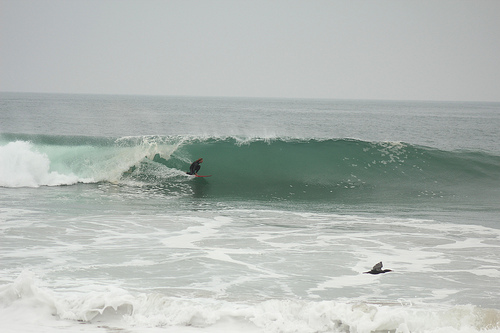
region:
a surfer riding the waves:
[181, 153, 215, 180]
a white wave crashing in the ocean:
[7, 131, 156, 191]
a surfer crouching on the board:
[178, 155, 215, 180]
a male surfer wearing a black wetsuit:
[183, 154, 217, 181]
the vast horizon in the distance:
[7, 82, 496, 110]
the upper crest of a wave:
[183, 123, 413, 157]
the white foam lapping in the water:
[8, 268, 163, 329]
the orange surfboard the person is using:
[180, 150, 218, 185]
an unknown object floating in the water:
[365, 258, 398, 281]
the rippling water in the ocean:
[305, 103, 472, 133]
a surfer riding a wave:
[176, 152, 217, 189]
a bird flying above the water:
[326, 242, 426, 302]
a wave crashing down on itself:
[0, 113, 170, 200]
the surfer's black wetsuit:
[186, 160, 201, 172]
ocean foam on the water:
[42, 248, 322, 326]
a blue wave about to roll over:
[223, 123, 431, 203]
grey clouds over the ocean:
[178, 11, 450, 87]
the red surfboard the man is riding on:
[178, 167, 217, 189]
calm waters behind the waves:
[148, 96, 418, 129]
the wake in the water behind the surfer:
[121, 156, 188, 190]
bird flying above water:
[347, 249, 400, 286]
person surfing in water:
[163, 143, 223, 188]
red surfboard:
[175, 171, 218, 182]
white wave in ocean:
[1, 132, 177, 201]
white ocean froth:
[150, 220, 272, 274]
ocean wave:
[205, 128, 478, 194]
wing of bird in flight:
[365, 250, 386, 273]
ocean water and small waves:
[3, 211, 338, 331]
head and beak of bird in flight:
[384, 266, 396, 278]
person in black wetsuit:
[176, 155, 212, 183]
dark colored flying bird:
[359, 257, 403, 281]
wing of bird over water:
[368, 257, 388, 273]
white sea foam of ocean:
[188, 238, 292, 288]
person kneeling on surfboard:
[176, 154, 219, 187]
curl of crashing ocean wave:
[96, 139, 176, 190]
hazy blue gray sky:
[193, 29, 312, 80]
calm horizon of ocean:
[206, 85, 328, 123]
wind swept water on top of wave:
[201, 122, 290, 144]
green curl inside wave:
[229, 143, 326, 185]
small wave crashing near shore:
[33, 283, 208, 326]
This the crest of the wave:
[191, 134, 428, 156]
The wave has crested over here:
[1, 131, 181, 193]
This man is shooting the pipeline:
[99, 137, 236, 192]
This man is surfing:
[182, 152, 226, 187]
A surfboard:
[182, 171, 229, 185]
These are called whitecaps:
[6, 276, 264, 323]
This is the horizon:
[7, 80, 493, 120]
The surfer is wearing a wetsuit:
[186, 152, 208, 176]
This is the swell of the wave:
[124, 174, 492, 219]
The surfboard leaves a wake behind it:
[140, 156, 202, 186]